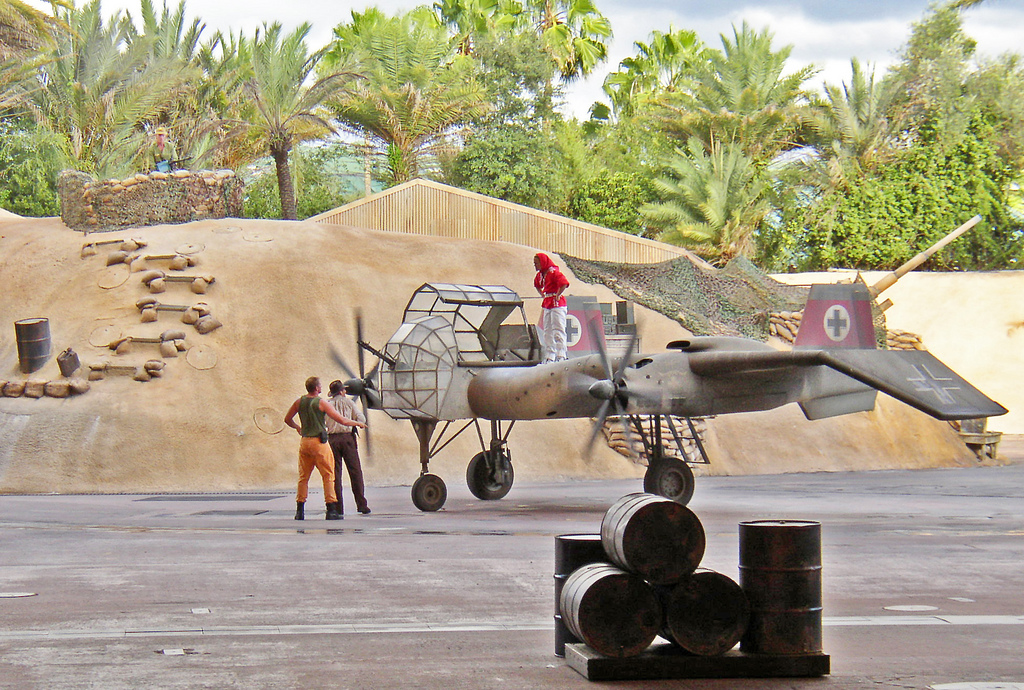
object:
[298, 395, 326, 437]
shirt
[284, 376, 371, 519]
man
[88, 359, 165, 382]
step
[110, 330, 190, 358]
step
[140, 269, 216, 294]
step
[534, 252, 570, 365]
man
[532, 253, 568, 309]
top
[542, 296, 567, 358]
pants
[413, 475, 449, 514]
wheel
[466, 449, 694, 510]
wheels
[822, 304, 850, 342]
cross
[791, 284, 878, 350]
stabilizer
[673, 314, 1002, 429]
stabilizers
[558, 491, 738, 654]
barrels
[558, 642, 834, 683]
pallet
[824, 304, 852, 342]
decal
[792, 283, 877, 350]
rudder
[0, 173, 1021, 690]
city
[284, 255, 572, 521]
people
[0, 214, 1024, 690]
outdoors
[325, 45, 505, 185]
tree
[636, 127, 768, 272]
tree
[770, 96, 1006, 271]
tree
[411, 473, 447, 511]
tire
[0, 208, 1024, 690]
airfield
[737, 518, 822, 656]
oil drum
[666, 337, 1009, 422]
wing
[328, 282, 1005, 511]
airplane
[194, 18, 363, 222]
palm tree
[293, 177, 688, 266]
roof top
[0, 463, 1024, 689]
airfield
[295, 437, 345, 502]
pants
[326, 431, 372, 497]
pants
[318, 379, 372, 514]
man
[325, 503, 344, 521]
shoe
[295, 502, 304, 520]
shoe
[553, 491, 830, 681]
barrels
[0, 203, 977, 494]
mound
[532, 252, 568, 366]
woman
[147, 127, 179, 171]
person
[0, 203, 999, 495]
hill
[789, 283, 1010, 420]
large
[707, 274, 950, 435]
barrel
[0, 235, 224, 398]
stairway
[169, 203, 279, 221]
field